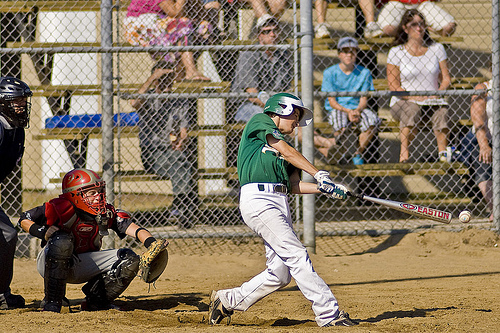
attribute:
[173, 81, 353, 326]
boy — young, swinging, wearing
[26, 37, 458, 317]
game — baseball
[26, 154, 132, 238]
helmet — catcher, baseball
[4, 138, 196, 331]
catcher — baseball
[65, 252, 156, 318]
pad — knee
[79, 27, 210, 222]
fence — metal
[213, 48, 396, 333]
player — baseball, playing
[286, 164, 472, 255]
bat — baseball, silver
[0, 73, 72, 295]
referee — black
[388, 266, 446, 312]
dirt — brown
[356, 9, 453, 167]
female — spectator, sitting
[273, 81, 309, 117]
helmet — green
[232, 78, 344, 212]
uniform — baseball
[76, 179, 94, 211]
mask — black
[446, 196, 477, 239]
ball — white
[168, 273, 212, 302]
line — golden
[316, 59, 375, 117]
shirt — blue